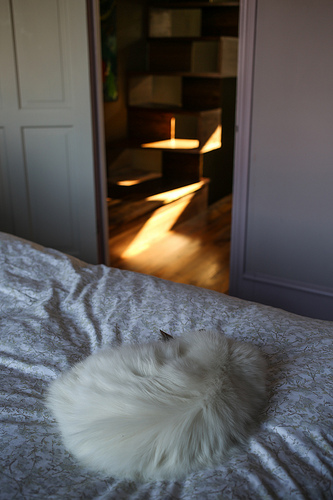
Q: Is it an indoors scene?
A: Yes, it is indoors.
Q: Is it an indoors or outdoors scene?
A: It is indoors.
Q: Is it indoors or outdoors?
A: It is indoors.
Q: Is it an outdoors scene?
A: No, it is indoors.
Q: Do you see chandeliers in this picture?
A: No, there are no chandeliers.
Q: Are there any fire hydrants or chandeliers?
A: No, there are no chandeliers or fire hydrants.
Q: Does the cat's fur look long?
A: Yes, the fur is long.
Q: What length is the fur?
A: The fur is long.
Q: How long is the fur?
A: The fur is long.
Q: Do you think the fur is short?
A: No, the fur is long.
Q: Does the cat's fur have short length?
A: No, the fur is long.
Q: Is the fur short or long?
A: The fur is long.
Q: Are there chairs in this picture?
A: No, there are no chairs.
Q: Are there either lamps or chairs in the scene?
A: No, there are no chairs or lamps.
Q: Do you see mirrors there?
A: No, there are no mirrors.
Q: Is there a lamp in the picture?
A: No, there are no lamps.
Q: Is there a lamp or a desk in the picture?
A: No, there are no lamps or desks.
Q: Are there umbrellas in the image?
A: No, there are no umbrellas.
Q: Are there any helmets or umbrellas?
A: No, there are no umbrellas or helmets.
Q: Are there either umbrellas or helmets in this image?
A: No, there are no umbrellas or helmets.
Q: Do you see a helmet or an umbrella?
A: No, there are no umbrellas or helmets.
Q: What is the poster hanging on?
A: The poster is hanging on the wall.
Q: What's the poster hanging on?
A: The poster is hanging on the wall.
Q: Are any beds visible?
A: Yes, there is a bed.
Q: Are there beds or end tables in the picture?
A: Yes, there is a bed.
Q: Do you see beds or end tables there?
A: Yes, there is a bed.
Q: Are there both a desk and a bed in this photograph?
A: No, there is a bed but no desks.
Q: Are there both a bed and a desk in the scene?
A: No, there is a bed but no desks.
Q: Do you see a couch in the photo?
A: No, there are no couches.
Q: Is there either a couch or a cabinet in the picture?
A: No, there are no couches or cabinets.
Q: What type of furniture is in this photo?
A: The furniture is a bed.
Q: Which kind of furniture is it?
A: The piece of furniture is a bed.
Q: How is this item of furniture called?
A: This is a bed.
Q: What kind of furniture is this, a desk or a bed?
A: This is a bed.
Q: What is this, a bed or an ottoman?
A: This is a bed.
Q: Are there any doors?
A: Yes, there is a door.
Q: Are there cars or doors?
A: Yes, there is a door.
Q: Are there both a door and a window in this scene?
A: No, there is a door but no windows.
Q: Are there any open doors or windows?
A: Yes, there is an open door.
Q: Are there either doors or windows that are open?
A: Yes, the door is open.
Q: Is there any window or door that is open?
A: Yes, the door is open.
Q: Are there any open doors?
A: Yes, there is an open door.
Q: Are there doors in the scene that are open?
A: Yes, there is a door that is open.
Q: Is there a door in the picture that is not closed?
A: Yes, there is a open door.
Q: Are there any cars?
A: No, there are no cars.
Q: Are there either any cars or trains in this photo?
A: No, there are no cars or trains.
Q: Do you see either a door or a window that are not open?
A: No, there is a door but it is open.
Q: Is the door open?
A: Yes, the door is open.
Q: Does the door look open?
A: Yes, the door is open.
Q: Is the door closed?
A: No, the door is open.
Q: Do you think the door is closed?
A: No, the door is open.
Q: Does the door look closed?
A: No, the door is open.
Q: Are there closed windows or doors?
A: No, there is a door but it is open.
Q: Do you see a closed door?
A: No, there is a door but it is open.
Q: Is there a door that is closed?
A: No, there is a door but it is open.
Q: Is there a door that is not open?
A: No, there is a door but it is open.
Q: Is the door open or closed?
A: The door is open.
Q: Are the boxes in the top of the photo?
A: Yes, the boxes are in the top of the image.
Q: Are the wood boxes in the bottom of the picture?
A: No, the boxes are in the top of the image.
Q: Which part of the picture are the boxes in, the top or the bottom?
A: The boxes are in the top of the image.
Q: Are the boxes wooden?
A: Yes, the boxes are wooden.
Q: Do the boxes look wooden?
A: Yes, the boxes are wooden.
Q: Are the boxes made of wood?
A: Yes, the boxes are made of wood.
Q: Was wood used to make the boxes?
A: Yes, the boxes are made of wood.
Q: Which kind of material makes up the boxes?
A: The boxes are made of wood.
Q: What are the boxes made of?
A: The boxes are made of wood.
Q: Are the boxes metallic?
A: No, the boxes are wooden.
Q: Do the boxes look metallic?
A: No, the boxes are wooden.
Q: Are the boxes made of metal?
A: No, the boxes are made of wood.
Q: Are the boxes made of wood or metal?
A: The boxes are made of wood.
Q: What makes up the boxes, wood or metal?
A: The boxes are made of wood.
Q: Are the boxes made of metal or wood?
A: The boxes are made of wood.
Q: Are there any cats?
A: Yes, there is a cat.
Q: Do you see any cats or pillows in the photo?
A: Yes, there is a cat.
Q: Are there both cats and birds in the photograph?
A: No, there is a cat but no birds.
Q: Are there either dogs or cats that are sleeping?
A: Yes, the cat is sleeping.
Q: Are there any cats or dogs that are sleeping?
A: Yes, the cat is sleeping.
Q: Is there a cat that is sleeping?
A: Yes, there is a cat that is sleeping.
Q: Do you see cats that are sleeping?
A: Yes, there is a cat that is sleeping.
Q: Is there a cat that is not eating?
A: Yes, there is a cat that is sleeping.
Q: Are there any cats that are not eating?
A: Yes, there is a cat that is sleeping.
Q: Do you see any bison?
A: No, there are no bison.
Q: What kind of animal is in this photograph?
A: The animal is a cat.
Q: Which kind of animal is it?
A: The animal is a cat.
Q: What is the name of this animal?
A: This is a cat.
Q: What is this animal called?
A: This is a cat.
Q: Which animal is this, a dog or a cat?
A: This is a cat.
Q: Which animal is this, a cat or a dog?
A: This is a cat.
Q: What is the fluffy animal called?
A: The animal is a cat.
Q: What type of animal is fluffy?
A: The animal is a cat.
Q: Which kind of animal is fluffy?
A: The animal is a cat.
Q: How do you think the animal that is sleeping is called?
A: The animal is a cat.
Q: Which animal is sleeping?
A: The animal is a cat.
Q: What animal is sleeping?
A: The animal is a cat.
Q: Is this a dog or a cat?
A: This is a cat.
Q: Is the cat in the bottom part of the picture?
A: Yes, the cat is in the bottom of the image.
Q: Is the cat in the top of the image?
A: No, the cat is in the bottom of the image.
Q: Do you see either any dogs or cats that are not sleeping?
A: No, there is a cat but it is sleeping.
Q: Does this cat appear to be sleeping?
A: Yes, the cat is sleeping.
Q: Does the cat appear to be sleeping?
A: Yes, the cat is sleeping.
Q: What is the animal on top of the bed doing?
A: The cat is sleeping.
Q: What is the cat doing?
A: The cat is sleeping.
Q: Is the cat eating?
A: No, the cat is sleeping.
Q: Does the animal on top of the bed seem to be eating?
A: No, the cat is sleeping.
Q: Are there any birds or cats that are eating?
A: No, there is a cat but it is sleeping.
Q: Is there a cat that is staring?
A: No, there is a cat but it is sleeping.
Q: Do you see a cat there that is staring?
A: No, there is a cat but it is sleeping.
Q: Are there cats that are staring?
A: No, there is a cat but it is sleeping.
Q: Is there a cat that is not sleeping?
A: No, there is a cat but it is sleeping.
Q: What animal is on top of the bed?
A: The cat is on top of the bed.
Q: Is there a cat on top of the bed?
A: Yes, there is a cat on top of the bed.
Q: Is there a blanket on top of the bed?
A: No, there is a cat on top of the bed.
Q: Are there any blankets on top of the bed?
A: No, there is a cat on top of the bed.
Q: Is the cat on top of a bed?
A: Yes, the cat is on top of a bed.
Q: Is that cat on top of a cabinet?
A: No, the cat is on top of a bed.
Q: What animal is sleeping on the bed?
A: The cat is sleeping on the bed.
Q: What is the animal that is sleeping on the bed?
A: The animal is a cat.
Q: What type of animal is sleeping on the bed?
A: The animal is a cat.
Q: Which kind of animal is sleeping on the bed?
A: The animal is a cat.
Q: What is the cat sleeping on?
A: The cat is sleeping on the bed.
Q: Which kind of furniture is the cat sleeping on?
A: The cat is sleeping on the bed.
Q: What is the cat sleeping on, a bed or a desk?
A: The cat is sleeping on a bed.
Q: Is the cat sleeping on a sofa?
A: No, the cat is sleeping on the bed.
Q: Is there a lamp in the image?
A: No, there are no lamps.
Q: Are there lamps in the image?
A: No, there are no lamps.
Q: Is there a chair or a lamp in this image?
A: No, there are no lamps or chairs.